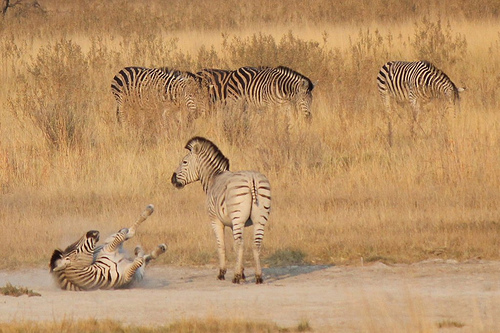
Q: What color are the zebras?
A: Black and white.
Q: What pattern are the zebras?
A: Striped.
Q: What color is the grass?
A: Brown.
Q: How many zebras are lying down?
A: 1.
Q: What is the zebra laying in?
A: Dirt.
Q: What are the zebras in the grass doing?
A: Eating.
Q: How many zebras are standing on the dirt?
A: 1.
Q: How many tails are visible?
A: 1.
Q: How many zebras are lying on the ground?
A: One.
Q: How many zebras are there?
A: Five.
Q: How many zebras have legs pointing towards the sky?
A: One.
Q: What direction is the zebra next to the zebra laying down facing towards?
A: Left.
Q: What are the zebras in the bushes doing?
A: Grazing.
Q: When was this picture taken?
A: Daytime.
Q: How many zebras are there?
A: 5.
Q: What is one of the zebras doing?
A: Laying on the ground.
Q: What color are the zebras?
A: Black and white.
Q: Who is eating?
A: 3 of the zebras.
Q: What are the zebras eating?
A: Grass.